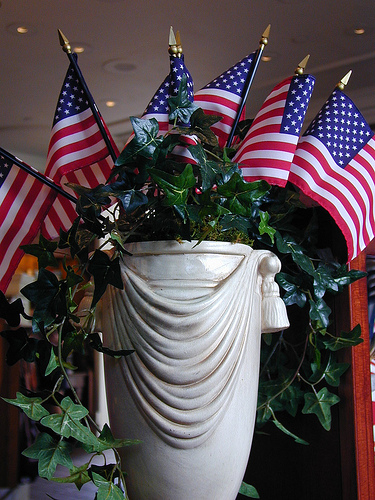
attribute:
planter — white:
[147, 290, 232, 388]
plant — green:
[154, 159, 192, 176]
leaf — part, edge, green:
[91, 195, 152, 225]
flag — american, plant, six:
[168, 71, 186, 74]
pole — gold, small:
[253, 25, 281, 35]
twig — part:
[197, 216, 202, 220]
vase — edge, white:
[241, 282, 255, 354]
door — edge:
[362, 95, 372, 107]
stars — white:
[231, 82, 241, 87]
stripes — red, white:
[221, 101, 233, 108]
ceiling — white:
[214, 18, 237, 30]